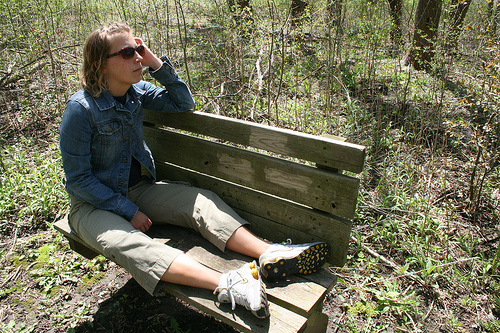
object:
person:
[57, 21, 328, 322]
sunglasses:
[103, 45, 145, 59]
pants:
[68, 179, 250, 300]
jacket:
[57, 55, 194, 221]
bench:
[50, 106, 366, 332]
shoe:
[260, 241, 331, 284]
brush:
[0, 142, 67, 225]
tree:
[406, 2, 442, 70]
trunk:
[328, 0, 343, 29]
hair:
[84, 23, 130, 98]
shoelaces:
[214, 277, 236, 312]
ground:
[1, 2, 499, 331]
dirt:
[80, 275, 108, 294]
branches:
[250, 47, 266, 120]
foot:
[219, 260, 270, 318]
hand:
[132, 36, 159, 70]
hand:
[131, 212, 152, 233]